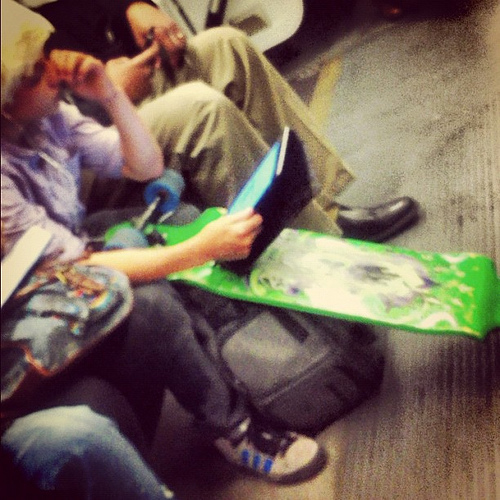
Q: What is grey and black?
A: Backpack.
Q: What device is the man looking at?
A: Tablet.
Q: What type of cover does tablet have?
A: Black.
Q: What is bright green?
A: Skateboard.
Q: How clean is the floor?
A: Dirty.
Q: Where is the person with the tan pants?
A: Left of boy.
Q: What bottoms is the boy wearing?
A: Jeans.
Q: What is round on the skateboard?
A: Wheels.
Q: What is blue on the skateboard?
A: Wheels.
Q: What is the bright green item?
A: A skateboard.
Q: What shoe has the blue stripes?
A: The athletic shoes.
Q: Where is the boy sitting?
A: On a chair.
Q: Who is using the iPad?
A: A boy.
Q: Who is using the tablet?
A: The boy.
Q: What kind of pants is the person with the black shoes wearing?
A: Brown khakis.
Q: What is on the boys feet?
A: Shoes.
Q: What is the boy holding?
A: A skateboard.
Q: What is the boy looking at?
A: A tablet computer.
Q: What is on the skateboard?
A: Wheels.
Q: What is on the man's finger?
A: A wedding ring.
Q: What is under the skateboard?
A: A backpack.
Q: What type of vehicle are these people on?
A: Train.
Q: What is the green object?
A: Skateboard.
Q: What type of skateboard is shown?
A: Longboard.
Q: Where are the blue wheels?
A: On skateboard.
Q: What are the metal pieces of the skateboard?
A: Trucks.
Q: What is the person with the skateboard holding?
A: Tablet.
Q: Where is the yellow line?
A: On ground.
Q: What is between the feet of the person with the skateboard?
A: Grey backpack.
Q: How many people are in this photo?
A: Three.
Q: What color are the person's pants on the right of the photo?
A: Tan.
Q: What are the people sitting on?
A: Bus.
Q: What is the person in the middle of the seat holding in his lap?
A: Skateboard.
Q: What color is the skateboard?
A: Green.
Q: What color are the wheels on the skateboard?
A: Blue.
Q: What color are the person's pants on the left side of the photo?
A: Jeans.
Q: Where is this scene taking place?
A: On carpet.